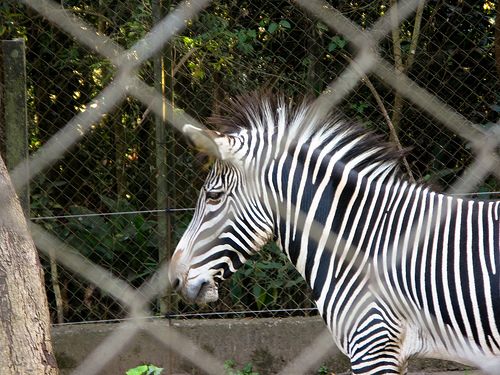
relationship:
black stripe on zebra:
[408, 194, 491, 317] [165, 89, 499, 374]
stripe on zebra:
[191, 246, 243, 266] [165, 89, 499, 374]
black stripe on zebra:
[438, 195, 470, 343] [165, 89, 499, 374]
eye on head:
[200, 185, 228, 204] [164, 113, 322, 308]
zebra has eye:
[192, 179, 232, 215] [200, 185, 228, 204]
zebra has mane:
[165, 89, 499, 374] [216, 82, 414, 177]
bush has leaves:
[30, 184, 308, 319] [97, 20, 273, 95]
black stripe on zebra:
[277, 118, 295, 254] [165, 89, 499, 374]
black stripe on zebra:
[301, 113, 357, 305] [159, 86, 498, 373]